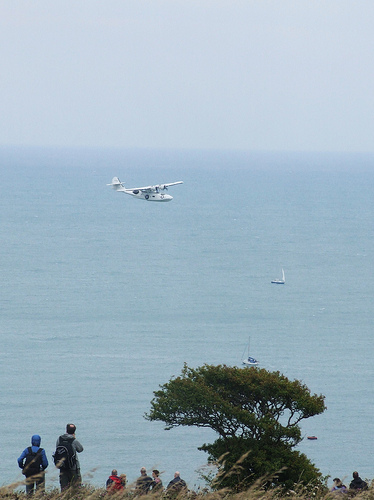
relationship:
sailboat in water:
[270, 266, 288, 289] [1, 148, 371, 492]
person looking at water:
[12, 436, 46, 498] [1, 148, 371, 492]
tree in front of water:
[146, 357, 327, 498] [1, 148, 371, 492]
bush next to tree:
[195, 430, 321, 496] [146, 357, 327, 498]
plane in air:
[104, 174, 185, 206] [1, 0, 371, 492]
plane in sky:
[104, 174, 185, 206] [1, 2, 371, 158]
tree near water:
[146, 357, 327, 498] [1, 148, 371, 492]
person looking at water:
[51, 422, 87, 495] [1, 148, 371, 492]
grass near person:
[3, 458, 371, 499] [12, 436, 46, 498]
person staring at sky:
[12, 436, 46, 498] [1, 2, 371, 158]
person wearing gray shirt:
[51, 422, 87, 495] [60, 434, 82, 450]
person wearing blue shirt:
[12, 436, 46, 498] [15, 432, 49, 476]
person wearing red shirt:
[102, 470, 131, 496] [102, 470, 131, 492]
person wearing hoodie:
[12, 436, 46, 498] [15, 432, 49, 476]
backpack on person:
[22, 445, 47, 478] [12, 436, 46, 498]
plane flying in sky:
[104, 174, 185, 206] [1, 2, 371, 158]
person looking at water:
[102, 470, 131, 496] [1, 148, 371, 492]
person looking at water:
[349, 469, 368, 499] [1, 148, 371, 492]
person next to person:
[12, 436, 46, 498] [51, 422, 87, 495]